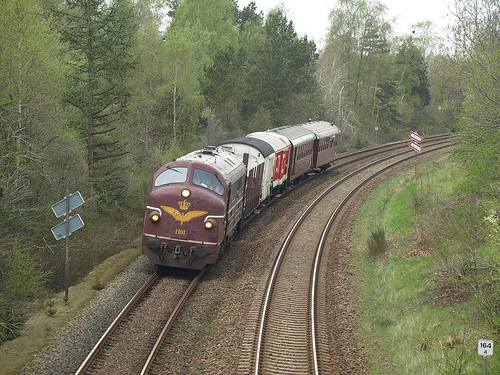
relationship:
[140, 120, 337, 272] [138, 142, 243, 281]
train has car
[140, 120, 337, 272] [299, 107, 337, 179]
train has car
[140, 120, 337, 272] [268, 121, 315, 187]
train has car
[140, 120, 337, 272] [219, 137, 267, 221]
train has car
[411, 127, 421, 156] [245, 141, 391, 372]
signs next to tracks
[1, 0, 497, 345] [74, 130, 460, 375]
trees line track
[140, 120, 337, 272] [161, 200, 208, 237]
train has design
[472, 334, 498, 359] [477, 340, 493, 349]
sign has lettering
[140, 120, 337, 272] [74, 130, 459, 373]
train on track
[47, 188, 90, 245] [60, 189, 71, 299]
sign on pole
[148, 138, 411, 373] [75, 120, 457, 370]
gravel between tracks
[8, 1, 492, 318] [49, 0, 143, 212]
area has tree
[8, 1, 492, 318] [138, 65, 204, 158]
area has tree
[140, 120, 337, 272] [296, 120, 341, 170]
train has car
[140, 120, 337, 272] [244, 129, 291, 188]
train has cart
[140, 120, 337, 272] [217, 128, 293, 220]
train has car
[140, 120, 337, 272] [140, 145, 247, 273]
train has car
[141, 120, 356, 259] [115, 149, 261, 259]
train has cart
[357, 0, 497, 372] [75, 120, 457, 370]
foliage lines tracks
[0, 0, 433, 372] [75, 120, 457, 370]
foliage lines tracks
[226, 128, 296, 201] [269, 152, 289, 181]
car has lettering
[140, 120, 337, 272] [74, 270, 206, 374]
train on a track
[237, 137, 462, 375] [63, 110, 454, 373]
track next to train track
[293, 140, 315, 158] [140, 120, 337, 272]
windows on side of train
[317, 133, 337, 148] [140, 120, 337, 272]
windows on side of train